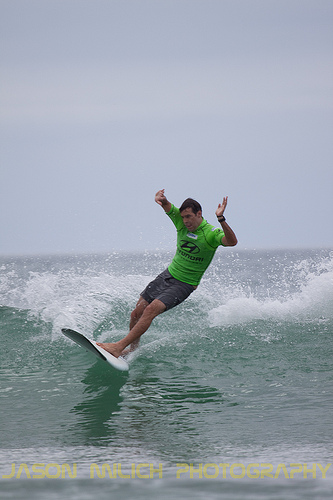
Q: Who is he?
A: A surfer.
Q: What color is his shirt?
A: Green.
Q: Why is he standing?
A: To balance.